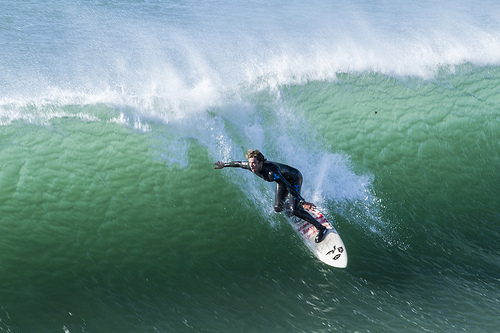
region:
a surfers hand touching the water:
[203, 147, 246, 179]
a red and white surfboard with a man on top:
[266, 189, 384, 287]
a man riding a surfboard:
[215, 128, 340, 256]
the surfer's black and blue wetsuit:
[266, 161, 331, 228]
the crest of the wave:
[2, 66, 489, 153]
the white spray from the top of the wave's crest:
[6, 1, 450, 53]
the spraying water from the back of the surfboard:
[279, 121, 390, 223]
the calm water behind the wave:
[1, 2, 323, 45]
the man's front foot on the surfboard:
[286, 206, 352, 244]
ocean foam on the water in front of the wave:
[36, 266, 479, 332]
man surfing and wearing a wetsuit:
[202, 135, 378, 296]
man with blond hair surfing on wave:
[189, 129, 371, 285]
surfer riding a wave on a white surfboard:
[97, 22, 406, 294]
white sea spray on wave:
[135, 32, 345, 140]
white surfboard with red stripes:
[277, 186, 379, 291]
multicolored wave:
[325, 59, 469, 275]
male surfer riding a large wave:
[207, 117, 379, 300]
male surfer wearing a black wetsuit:
[200, 131, 380, 297]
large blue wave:
[45, 46, 474, 326]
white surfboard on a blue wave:
[267, 185, 368, 290]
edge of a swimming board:
[324, 252, 359, 277]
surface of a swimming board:
[327, 240, 339, 267]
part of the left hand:
[304, 197, 316, 214]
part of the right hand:
[207, 148, 224, 177]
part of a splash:
[158, 105, 210, 180]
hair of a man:
[248, 147, 268, 159]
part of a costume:
[271, 166, 291, 197]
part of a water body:
[401, 127, 450, 180]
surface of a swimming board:
[309, 232, 334, 264]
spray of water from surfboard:
[307, 142, 386, 230]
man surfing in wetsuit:
[208, 150, 326, 245]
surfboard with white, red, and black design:
[263, 177, 350, 272]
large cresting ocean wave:
[14, 132, 207, 289]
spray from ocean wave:
[12, 19, 497, 91]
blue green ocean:
[15, 15, 495, 310]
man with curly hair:
[210, 139, 333, 248]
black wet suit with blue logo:
[261, 155, 328, 244]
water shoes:
[314, 223, 328, 245]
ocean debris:
[372, 107, 379, 116]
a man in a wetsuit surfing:
[212, 148, 347, 273]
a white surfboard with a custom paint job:
[279, 192, 347, 271]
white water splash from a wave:
[0, 29, 499, 120]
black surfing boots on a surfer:
[314, 223, 328, 241]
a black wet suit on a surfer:
[223, 162, 328, 242]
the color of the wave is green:
[1, 62, 499, 332]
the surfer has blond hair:
[243, 149, 265, 163]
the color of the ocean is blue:
[1, 1, 498, 101]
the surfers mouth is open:
[248, 158, 260, 172]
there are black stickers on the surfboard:
[324, 243, 344, 263]